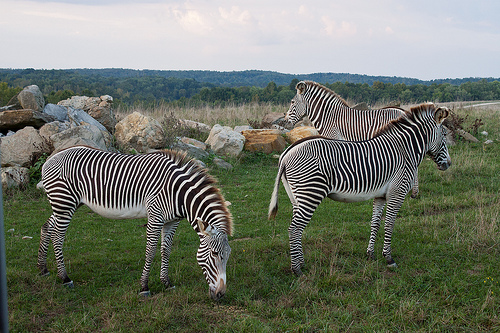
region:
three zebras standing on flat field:
[0, 68, 477, 310]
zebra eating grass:
[36, 150, 239, 306]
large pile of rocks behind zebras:
[5, 87, 405, 184]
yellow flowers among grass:
[480, 275, 495, 297]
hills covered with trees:
[9, 64, 496, 106]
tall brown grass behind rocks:
[140, 100, 288, 140]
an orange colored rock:
[243, 129, 279, 154]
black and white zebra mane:
[363, 103, 445, 140]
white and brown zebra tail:
[263, 161, 287, 226]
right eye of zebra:
[210, 246, 221, 261]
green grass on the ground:
[286, 277, 473, 329]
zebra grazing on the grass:
[36, 131, 235, 289]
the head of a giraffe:
[193, 219, 243, 288]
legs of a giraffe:
[133, 218, 187, 295]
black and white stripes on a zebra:
[61, 156, 166, 208]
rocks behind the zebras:
[18, 93, 108, 143]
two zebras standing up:
[258, 75, 471, 268]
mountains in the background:
[31, 69, 242, 93]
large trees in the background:
[1, 70, 228, 95]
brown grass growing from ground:
[138, 97, 257, 119]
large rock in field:
[1, 160, 38, 191]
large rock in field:
[3, 124, 47, 164]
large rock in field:
[43, 117, 92, 157]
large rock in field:
[3, 103, 35, 128]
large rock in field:
[40, 96, 72, 122]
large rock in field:
[10, 79, 52, 114]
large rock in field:
[110, 101, 169, 150]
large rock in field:
[163, 131, 214, 151]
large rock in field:
[201, 118, 251, 165]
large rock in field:
[233, 116, 291, 157]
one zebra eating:
[32, 146, 230, 304]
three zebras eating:
[21, 83, 453, 296]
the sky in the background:
[44, 13, 424, 62]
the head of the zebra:
[190, 218, 238, 300]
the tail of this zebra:
[267, 163, 284, 219]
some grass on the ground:
[242, 296, 484, 319]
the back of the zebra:
[70, 142, 168, 169]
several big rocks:
[7, 91, 235, 145]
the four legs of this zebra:
[288, 195, 398, 272]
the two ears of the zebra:
[431, 103, 449, 123]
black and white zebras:
[55, 71, 462, 295]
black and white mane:
[337, 103, 438, 153]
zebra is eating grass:
[34, 123, 252, 281]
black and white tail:
[252, 140, 300, 220]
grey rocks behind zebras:
[21, 97, 253, 204]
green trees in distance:
[121, 64, 495, 116]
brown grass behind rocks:
[147, 94, 341, 146]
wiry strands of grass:
[248, 283, 445, 330]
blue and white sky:
[180, 1, 320, 65]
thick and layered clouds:
[180, 3, 378, 64]